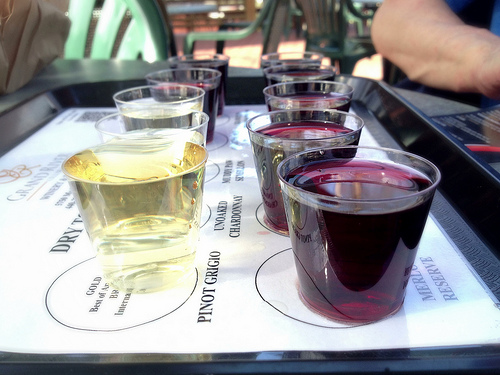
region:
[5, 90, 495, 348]
placemat describing sample types of wine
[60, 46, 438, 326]
plastic cups filled with white and red wines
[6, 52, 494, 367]
black tray holding wine for tasting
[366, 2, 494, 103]
person's elbow and forearm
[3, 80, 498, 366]
white paper on tray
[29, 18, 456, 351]
small cups on a tray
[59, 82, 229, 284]
white wines in cup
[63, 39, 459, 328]
different kinds of wines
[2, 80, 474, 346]
black labels of wine on paper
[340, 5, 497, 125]
person in the background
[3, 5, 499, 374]
this is a wine tasting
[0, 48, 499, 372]
two rows of cups on top of tray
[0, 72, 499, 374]
paper with words on tray top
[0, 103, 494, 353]
white paper with words and circles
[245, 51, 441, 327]
row of cups on paper circles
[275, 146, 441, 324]
red wine in short clear cup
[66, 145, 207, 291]
cup full of white wine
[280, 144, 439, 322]
light reflection on surface of liquid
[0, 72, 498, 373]
edge of black rectangle tray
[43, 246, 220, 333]
two words under black circle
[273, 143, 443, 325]
shot glass of red wine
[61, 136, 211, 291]
shot glass of white wine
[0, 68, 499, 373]
black tray of wine samples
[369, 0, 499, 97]
person's right arm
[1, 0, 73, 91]
arm of coat jacket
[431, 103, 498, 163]
restaurant menu with black background and white text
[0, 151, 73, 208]
name and logo of wine bar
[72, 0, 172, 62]
green chair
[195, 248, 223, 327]
name of one of the white wine samples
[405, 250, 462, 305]
name of one of the red wine samples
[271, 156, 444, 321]
glass on a table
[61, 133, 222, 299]
glass on a table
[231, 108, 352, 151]
glass on a table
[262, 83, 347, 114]
glass on a table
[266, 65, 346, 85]
glass on a table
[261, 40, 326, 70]
glass on a table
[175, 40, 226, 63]
glass on a table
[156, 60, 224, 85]
glass on a table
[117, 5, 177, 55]
chair near a table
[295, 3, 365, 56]
chair near a table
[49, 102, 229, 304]
gold glass of wine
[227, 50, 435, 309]
glasses of red wine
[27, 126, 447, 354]
small glasses of wine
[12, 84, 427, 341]
white mat under glasses